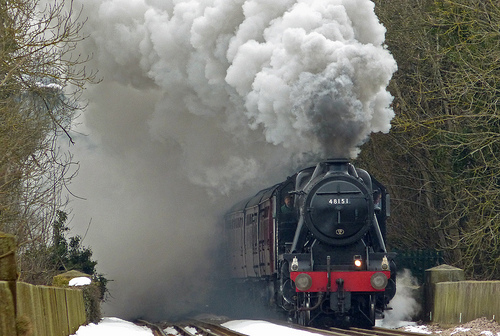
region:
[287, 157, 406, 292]
the front of the train is black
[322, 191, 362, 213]
the numbers on the front are white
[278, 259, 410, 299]
the bumper is red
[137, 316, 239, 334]
the tracks are brown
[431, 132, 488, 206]
the tress's have some green leaves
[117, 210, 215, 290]
the smoke closest to the ground is grey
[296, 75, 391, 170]
the smoke coming out of the stack has black in it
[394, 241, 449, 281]
the gate is green in color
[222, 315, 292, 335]
the snow is white in color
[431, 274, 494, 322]
the fence has a yellowish grey color to it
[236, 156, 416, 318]
Black and red train engine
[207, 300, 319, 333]
Light snow on the ground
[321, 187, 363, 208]
The engine number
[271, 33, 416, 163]
Black and white smoke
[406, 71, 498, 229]
Leafless trees on the side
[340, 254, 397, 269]
A head light on the train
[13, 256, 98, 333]
A brick wall along the tracks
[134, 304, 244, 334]
A set of train tracks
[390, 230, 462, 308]
A fence lining the side of the tracks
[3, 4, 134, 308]
Trees on the side of the train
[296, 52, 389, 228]
Steam coming from a train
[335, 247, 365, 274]
Lit headlight on train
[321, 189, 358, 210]
Train's identification number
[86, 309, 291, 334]
Snow on train tracks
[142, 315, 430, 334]
Two sets of train tracks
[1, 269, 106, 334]
Short wooden barrier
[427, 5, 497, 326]
Leafless trees behind wooden barrier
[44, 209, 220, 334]
Small evergreen near train tracks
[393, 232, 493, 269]
Green wooden fence behind trees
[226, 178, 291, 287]
Red and black train cars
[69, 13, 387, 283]
the train is steamy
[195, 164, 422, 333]
Black train on rails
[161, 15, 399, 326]
Black train blowing gray smoke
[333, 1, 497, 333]
Trees on the side of a train railway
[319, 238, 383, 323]
Train light on the front of a train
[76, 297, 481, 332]
Snow on train rails.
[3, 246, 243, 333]
Small wooden fence on the side of train rails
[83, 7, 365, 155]
Gray plume of smoke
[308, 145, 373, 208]
Train number on train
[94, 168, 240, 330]
Gray smoke cloud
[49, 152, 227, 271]
Small bush surrounded by smoke